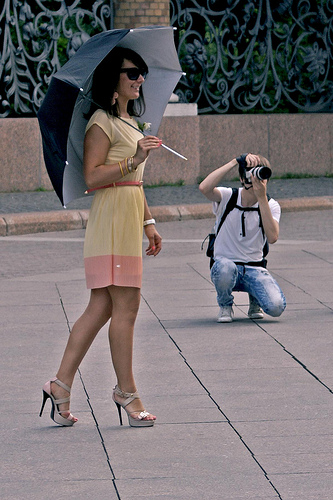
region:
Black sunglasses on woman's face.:
[121, 63, 158, 92]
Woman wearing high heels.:
[44, 380, 163, 430]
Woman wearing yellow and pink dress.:
[89, 125, 140, 283]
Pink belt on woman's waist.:
[93, 175, 164, 202]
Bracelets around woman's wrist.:
[109, 152, 160, 188]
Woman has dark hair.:
[79, 49, 127, 104]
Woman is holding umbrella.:
[41, 64, 197, 196]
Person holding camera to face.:
[232, 139, 283, 240]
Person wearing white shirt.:
[209, 203, 258, 248]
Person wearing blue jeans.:
[207, 267, 299, 308]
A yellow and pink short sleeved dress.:
[82, 113, 149, 289]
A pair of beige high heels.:
[37, 378, 158, 429]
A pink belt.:
[89, 179, 144, 188]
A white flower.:
[137, 121, 151, 133]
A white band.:
[144, 218, 157, 225]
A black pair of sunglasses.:
[120, 66, 145, 81]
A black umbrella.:
[36, 26, 188, 206]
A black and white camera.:
[234, 155, 273, 184]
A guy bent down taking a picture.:
[201, 133, 288, 330]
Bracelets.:
[117, 157, 135, 176]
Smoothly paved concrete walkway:
[79, 336, 332, 472]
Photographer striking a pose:
[191, 148, 289, 325]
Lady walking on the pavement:
[28, 20, 193, 437]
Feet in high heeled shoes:
[38, 373, 158, 432]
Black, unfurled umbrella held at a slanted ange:
[33, 21, 188, 211]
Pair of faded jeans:
[208, 256, 288, 319]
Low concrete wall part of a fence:
[2, 109, 331, 196]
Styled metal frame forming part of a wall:
[2, 3, 328, 119]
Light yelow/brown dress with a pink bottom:
[74, 105, 152, 294]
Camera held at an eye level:
[234, 150, 271, 186]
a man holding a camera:
[207, 146, 297, 318]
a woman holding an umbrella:
[56, 27, 180, 448]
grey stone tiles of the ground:
[210, 363, 315, 485]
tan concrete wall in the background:
[192, 120, 322, 155]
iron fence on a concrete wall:
[182, 1, 327, 121]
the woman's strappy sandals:
[34, 369, 163, 432]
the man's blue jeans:
[203, 254, 291, 329]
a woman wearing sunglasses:
[48, 30, 177, 190]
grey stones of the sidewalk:
[150, 187, 194, 200]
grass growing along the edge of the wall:
[274, 165, 326, 183]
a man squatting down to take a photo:
[198, 148, 298, 319]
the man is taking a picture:
[199, 149, 290, 323]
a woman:
[26, 20, 190, 440]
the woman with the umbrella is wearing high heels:
[15, 22, 193, 430]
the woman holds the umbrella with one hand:
[17, 19, 197, 429]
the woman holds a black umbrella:
[18, 25, 194, 450]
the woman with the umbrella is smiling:
[25, 19, 191, 436]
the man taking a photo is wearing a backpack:
[196, 144, 289, 326]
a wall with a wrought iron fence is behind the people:
[3, 1, 331, 164]